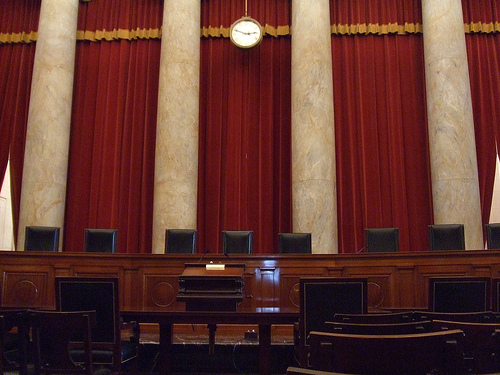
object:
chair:
[55, 274, 121, 311]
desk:
[120, 304, 303, 374]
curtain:
[0, 2, 499, 263]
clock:
[227, 17, 263, 50]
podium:
[177, 258, 247, 311]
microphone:
[196, 248, 212, 266]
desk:
[0, 248, 499, 334]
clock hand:
[232, 27, 246, 36]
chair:
[300, 277, 369, 366]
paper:
[205, 263, 225, 272]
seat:
[164, 228, 199, 255]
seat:
[306, 330, 462, 374]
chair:
[221, 229, 253, 254]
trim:
[0, 21, 499, 42]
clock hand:
[247, 30, 263, 35]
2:
[255, 27, 258, 33]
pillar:
[152, 1, 200, 250]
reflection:
[250, 261, 285, 311]